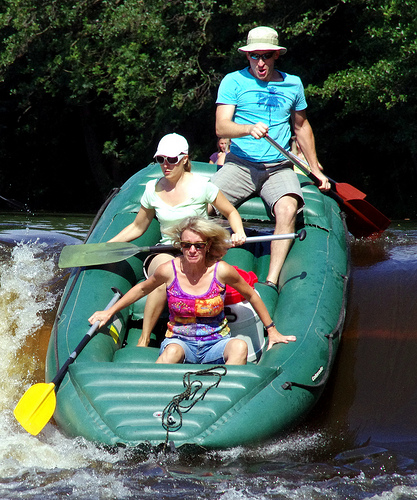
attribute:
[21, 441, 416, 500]
river — murky, brown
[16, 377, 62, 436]
paddle — yellow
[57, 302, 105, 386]
paddle handle — black, gray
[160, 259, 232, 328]
tank top — floral, multi colored, purple, pink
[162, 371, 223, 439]
rope — black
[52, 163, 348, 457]
raft — green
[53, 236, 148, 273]
paddle — green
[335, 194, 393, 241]
paddle — red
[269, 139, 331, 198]
paddle handle — black, gray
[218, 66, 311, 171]
shirt — blue, light blue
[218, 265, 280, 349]
canister — red, white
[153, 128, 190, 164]
baseball cap — white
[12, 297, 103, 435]
oar — yellow, silver, black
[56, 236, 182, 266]
oar — green, black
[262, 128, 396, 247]
oar — red, silver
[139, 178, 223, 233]
blouse — light green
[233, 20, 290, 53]
brimmed hat — light brown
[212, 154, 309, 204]
shorts — blue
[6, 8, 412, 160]
trees — green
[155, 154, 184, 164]
sunglasses — white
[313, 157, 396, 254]
oars — red